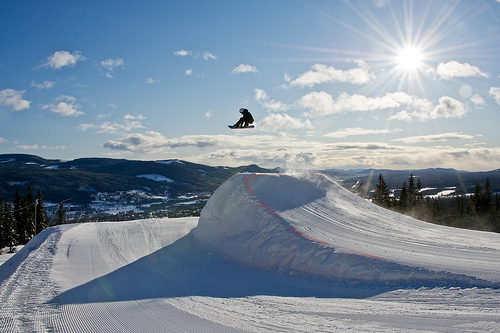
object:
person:
[232, 106, 256, 126]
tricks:
[231, 108, 258, 126]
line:
[245, 173, 282, 221]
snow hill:
[1, 147, 74, 194]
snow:
[135, 172, 175, 183]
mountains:
[0, 152, 278, 217]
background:
[0, 147, 300, 257]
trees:
[0, 184, 47, 245]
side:
[0, 231, 38, 275]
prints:
[246, 306, 307, 323]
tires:
[236, 307, 314, 324]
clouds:
[299, 63, 416, 121]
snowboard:
[227, 123, 260, 130]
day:
[3, 0, 486, 175]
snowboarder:
[227, 106, 256, 132]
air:
[203, 48, 293, 83]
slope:
[237, 171, 395, 243]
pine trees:
[370, 173, 425, 212]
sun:
[391, 47, 426, 78]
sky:
[254, 2, 499, 124]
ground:
[124, 282, 244, 332]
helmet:
[240, 109, 243, 114]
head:
[238, 107, 248, 112]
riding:
[229, 114, 257, 130]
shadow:
[47, 231, 493, 305]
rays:
[375, 28, 439, 50]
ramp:
[237, 171, 332, 202]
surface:
[387, 234, 487, 259]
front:
[227, 109, 239, 126]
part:
[67, 1, 107, 14]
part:
[78, 230, 118, 246]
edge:
[12, 238, 43, 265]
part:
[129, 314, 151, 323]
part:
[73, 170, 88, 178]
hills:
[0, 152, 223, 208]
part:
[247, 125, 255, 130]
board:
[227, 124, 254, 129]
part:
[58, 220, 64, 223]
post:
[65, 203, 73, 224]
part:
[19, 192, 39, 204]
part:
[242, 115, 252, 121]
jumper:
[229, 106, 258, 130]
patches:
[175, 301, 197, 316]